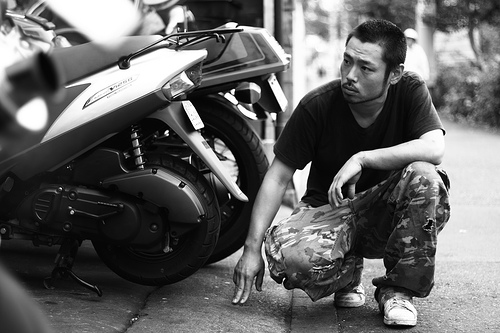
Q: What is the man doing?
A: Kneeling.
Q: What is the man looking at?
A: Motorcycle.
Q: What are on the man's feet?
A: Sneakers.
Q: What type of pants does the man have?
A: Camo.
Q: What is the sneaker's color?
A: White.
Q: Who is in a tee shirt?
A: Kneeling man.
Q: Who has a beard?
A: Kneeling man.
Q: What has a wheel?
A: Motorbike.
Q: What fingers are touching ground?
A: Index and middle.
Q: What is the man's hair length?
A: Short.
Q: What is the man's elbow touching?
A: Leg.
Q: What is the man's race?
A: Asian.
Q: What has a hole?
A: Pant leg.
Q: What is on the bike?
A: Tire.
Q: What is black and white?
A: Photo.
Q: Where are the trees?
A: Behind the man.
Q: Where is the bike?
A: Next to man.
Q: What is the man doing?
A: Kneeling.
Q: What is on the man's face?
A: A beard.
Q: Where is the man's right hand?
A: On the ground.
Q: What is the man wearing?
A: A shirt.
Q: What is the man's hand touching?
A: The ground.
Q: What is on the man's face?
A: A beard.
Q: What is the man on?
A: Asphalt.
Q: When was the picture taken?
A: Daytime.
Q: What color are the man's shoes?
A: White.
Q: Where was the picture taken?
A: At a motorcycle shop.